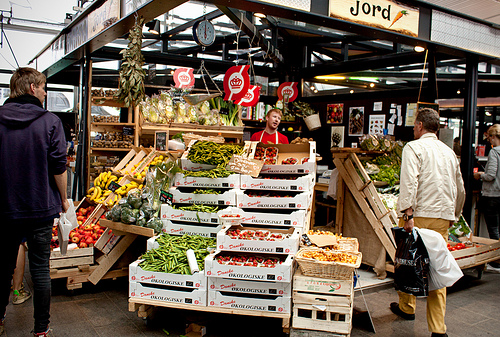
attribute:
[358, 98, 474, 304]
man — behind, walking, holding, carrying, black, wearing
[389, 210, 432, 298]
bag — black, white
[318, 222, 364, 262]
vegetable — orange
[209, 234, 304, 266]
case — wood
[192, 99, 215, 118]
orange — yellow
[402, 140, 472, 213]
jacket — white, gray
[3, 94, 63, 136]
hoody — blue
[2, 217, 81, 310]
jean — blue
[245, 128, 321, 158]
shirt — red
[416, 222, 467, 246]
pant — brown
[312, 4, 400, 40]
word — jord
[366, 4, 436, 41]
carrot — image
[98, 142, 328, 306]
fruit — different, fresh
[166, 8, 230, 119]
scale — one, hanging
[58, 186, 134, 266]
apple — red, tray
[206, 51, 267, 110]
sign — red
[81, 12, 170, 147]
good — hanging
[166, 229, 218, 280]
bean — green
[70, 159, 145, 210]
banana — yellow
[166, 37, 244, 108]
machine — weight